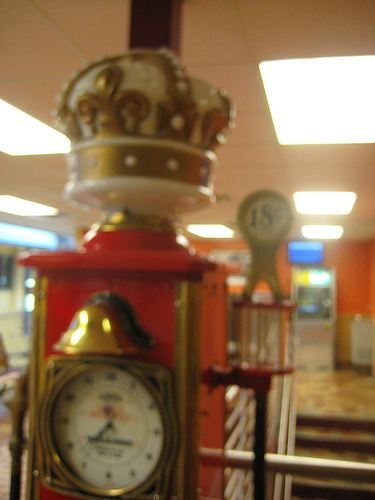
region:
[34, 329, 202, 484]
Clock on a display.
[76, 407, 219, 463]
hands on the clock.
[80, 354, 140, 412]
Numbers on the clock.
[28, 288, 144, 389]
Metal on the clock.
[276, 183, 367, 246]
Lights in the ceiling.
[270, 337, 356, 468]
Steps in the background.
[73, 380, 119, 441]
Black hands on the clock.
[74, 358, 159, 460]
Black numbers on the clock.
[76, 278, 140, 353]
Shine on the gold.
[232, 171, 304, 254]
Number on a sign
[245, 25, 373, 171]
Large light fixture hanging in the ceiling.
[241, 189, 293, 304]
Aisle marker eighteen on top of a shelf.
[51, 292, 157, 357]
Gold bell with lights showing on it.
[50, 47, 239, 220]
Royalty crown place atop of candy machine.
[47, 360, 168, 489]
The blurry face of a clock with numbers on it.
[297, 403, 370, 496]
Store stairs leading to a lower level.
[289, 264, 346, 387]
Exit doorway of an antique store.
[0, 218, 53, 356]
Entrance of an clock shop.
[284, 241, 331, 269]
A blue sign on an orange wall.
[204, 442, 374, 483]
Protection rail over a stairway.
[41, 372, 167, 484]
The clock is white.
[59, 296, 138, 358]
The bell is gold.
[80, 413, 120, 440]
The hands are black.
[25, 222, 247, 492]
The light is red.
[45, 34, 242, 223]
A crown is on top of the clock.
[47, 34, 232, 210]
The crown is gold and white.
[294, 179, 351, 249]
The lights are on.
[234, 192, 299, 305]
The sign is gold.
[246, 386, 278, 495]
The pole is black.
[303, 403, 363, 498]
The steps are brown.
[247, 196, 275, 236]
The number eighteen on a post.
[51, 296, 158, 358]
The gold bell reflects the room's light.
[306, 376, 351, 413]
Beige wooden floor tiles.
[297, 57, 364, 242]
Bright florescent bright lights.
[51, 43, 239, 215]
A white and gold royalty crown.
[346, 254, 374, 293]
An orange painted wall.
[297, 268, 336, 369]
The door of a clock store.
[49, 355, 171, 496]
Time clock with face numbers.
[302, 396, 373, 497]
Staircase leading downstairs.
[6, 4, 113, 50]
White and beige ceiling tile.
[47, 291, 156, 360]
gold bell above the clock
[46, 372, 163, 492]
black and white clock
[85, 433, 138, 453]
black writing on clock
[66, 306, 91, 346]
light shining on the bell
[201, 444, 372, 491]
thin silver railing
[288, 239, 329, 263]
monitor screen is blue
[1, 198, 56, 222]
light shining on the ceiling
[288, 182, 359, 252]
two lights on the ceiling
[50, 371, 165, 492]
black numbers around the circumference of the clock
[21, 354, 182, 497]
gold circle around the clock